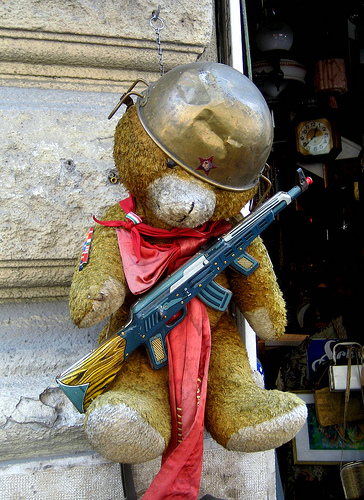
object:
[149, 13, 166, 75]
chain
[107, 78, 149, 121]
handle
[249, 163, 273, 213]
handle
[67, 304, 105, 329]
paw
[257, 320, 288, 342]
paw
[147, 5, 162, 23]
hook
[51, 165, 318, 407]
rifle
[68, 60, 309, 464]
bear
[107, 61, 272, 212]
pan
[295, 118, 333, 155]
clock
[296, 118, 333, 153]
hands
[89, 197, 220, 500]
red scarf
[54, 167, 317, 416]
gun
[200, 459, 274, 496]
mat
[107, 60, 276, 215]
bowl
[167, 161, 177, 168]
eye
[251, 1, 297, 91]
lamp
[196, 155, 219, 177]
insignia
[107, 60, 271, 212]
helmet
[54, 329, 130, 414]
butt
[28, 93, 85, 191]
wall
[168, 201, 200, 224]
nose